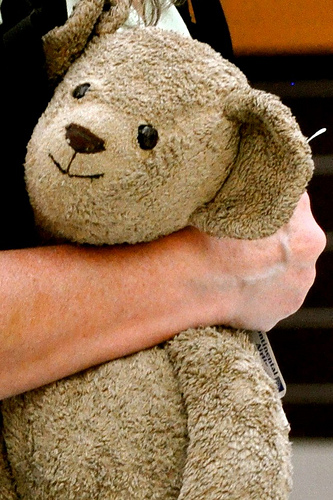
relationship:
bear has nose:
[20, 3, 297, 498] [65, 117, 107, 163]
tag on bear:
[235, 322, 297, 404] [20, 3, 297, 498]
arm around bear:
[1, 187, 324, 410] [20, 3, 297, 498]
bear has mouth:
[20, 3, 297, 498] [45, 147, 113, 190]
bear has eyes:
[20, 3, 297, 498] [69, 71, 163, 155]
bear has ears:
[20, 3, 297, 498] [39, 1, 307, 241]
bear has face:
[20, 3, 297, 498] [41, 78, 170, 212]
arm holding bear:
[1, 187, 324, 410] [20, 3, 297, 498]